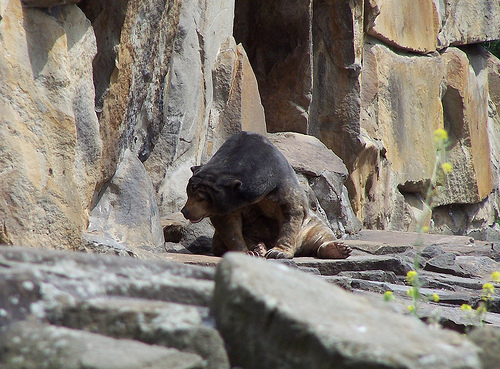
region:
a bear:
[185, 125, 325, 252]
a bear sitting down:
[188, 122, 344, 259]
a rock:
[242, 255, 407, 344]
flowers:
[386, 261, 441, 319]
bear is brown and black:
[169, 129, 341, 269]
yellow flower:
[429, 128, 452, 147]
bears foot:
[318, 235, 356, 254]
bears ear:
[218, 173, 243, 190]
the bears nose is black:
[176, 202, 187, 217]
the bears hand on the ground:
[267, 239, 299, 264]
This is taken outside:
[31, 34, 498, 352]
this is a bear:
[166, 128, 371, 294]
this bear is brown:
[172, 135, 322, 262]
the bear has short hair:
[181, 130, 333, 269]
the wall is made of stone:
[31, 23, 273, 124]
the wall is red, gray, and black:
[361, 27, 478, 145]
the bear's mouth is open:
[181, 189, 214, 236]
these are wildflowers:
[382, 153, 456, 342]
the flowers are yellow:
[374, 125, 489, 322]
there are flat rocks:
[52, 258, 302, 364]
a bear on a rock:
[179, 129, 355, 258]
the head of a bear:
[181, 162, 236, 223]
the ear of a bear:
[214, 169, 248, 196]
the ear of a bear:
[186, 159, 202, 178]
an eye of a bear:
[194, 184, 209, 201]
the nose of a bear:
[176, 203, 191, 218]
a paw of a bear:
[261, 243, 295, 261]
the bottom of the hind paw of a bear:
[316, 236, 353, 260]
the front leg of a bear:
[261, 196, 306, 263]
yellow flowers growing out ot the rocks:
[374, 262, 446, 320]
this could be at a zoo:
[10, 32, 425, 312]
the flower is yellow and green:
[378, 110, 445, 307]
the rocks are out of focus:
[13, 250, 337, 352]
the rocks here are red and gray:
[30, 23, 269, 165]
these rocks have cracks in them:
[60, 20, 255, 126]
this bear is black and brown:
[185, 122, 319, 250]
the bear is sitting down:
[194, 144, 413, 327]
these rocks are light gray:
[53, 256, 368, 355]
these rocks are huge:
[366, 46, 498, 108]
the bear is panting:
[171, 144, 333, 267]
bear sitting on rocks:
[176, 128, 352, 262]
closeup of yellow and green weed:
[378, 125, 498, 331]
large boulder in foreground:
[211, 248, 498, 367]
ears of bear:
[188, 163, 241, 191]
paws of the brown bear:
[236, 235, 355, 262]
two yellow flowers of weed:
[428, 124, 455, 176]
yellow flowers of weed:
[383, 267, 440, 314]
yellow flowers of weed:
[459, 268, 499, 317]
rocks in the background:
[2, 0, 264, 132]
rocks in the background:
[306, 2, 498, 124]